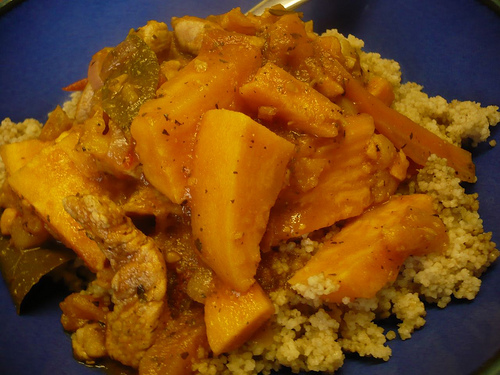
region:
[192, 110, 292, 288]
vegetable is cooked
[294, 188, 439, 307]
vegetable is cooked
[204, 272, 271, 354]
vegetable is cooked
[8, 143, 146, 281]
vegetable is cooked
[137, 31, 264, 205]
vegetable is cooked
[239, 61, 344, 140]
vegetable is cooked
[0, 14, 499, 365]
grain has been prepared as a meal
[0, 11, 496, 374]
grain is covered in vegetables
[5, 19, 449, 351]
vegetables sit on top of a grain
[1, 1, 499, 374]
plate has food on it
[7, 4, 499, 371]
a pile of food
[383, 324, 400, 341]
a bit of rice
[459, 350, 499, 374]
edge of the plate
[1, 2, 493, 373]
food on a plate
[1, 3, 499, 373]
vegetables on top of the rice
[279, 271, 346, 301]
rice stuck to the orange piece of food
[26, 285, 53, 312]
shadow on the plate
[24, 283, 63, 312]
shadow from the food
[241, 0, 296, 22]
silver handle on the plate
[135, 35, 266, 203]
vegetable is on rice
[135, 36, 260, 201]
vegetable is cooked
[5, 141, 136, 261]
vegetable is cooked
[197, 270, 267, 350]
vegetable is cooked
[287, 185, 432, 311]
vegetable is cooked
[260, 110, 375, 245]
vegetable is cooked so that it can be eaten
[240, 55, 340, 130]
vegetable is cooked so it can be eaten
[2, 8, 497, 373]
grain is covered in cooked vegetables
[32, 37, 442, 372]
a plate of food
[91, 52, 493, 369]
food on a plate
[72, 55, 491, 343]
cooked food on a blue plate